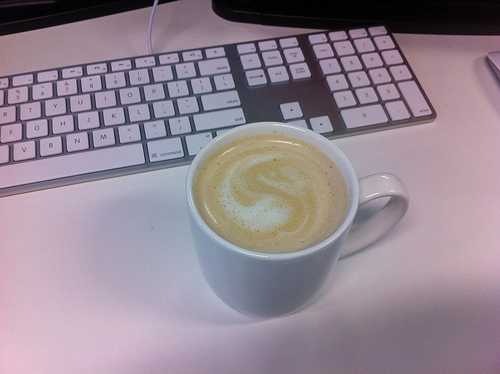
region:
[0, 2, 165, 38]
darkness behind edge of white table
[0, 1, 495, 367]
white table with flat and curved edge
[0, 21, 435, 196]
flat gray keyboard with white butons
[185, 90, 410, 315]
ceramic white mug on table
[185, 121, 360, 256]
swirl of foam on top of coffee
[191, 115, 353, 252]
yin-yang shapes on top of beverage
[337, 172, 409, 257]
curve of white handle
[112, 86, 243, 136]
square shapes next to rectangles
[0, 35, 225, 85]
border of small rectangles on edge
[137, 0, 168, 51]
curved wire leading to keyboard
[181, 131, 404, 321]
a cup of coffee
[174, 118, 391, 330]
a cup of coffee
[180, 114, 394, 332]
a cup of coffee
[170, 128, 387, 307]
a cup of coffee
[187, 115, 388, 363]
a cup of coffee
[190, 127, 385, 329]
white mug on the table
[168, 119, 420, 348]
white mug on the table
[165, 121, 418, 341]
white mug on the table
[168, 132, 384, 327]
white mug on the table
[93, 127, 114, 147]
the white letter M on the keyboard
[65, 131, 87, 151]
the white letter N on the keyboard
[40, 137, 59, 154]
the white letter B on the keyboard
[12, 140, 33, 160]
the white letter V on the keyboard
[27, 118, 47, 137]
the white letter G on the keyboard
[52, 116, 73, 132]
the white letter H on the keyboard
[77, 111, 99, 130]
the white letter J on the keyboard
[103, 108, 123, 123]
the white letter K on the keyboard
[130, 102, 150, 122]
the white letter L on the keyboard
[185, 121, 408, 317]
A white mug of coffee.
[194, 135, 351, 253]
Cream swirling in a coffee mug.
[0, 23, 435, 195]
Silver and white membrane keyboard.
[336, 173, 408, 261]
Handle of a coffee mug.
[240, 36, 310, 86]
Keys on a membrane keyboard.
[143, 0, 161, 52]
Cord of a keyboard.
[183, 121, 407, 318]
A cup full of creamed coffee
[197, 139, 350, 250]
Coffee in a white coffee mug.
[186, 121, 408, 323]
A white coffee mug on a white desk surface.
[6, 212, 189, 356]
White surface of a desk.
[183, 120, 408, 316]
a white coffee mug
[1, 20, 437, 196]
a white Apple USB keyboard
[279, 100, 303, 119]
a white up arrow key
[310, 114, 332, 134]
a white right arrow key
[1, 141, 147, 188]
a white space bar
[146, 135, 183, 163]
a white command key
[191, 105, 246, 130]
a white shift key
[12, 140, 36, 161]
a white V key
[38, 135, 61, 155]
a white B key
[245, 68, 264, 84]
A key on a keyboard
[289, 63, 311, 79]
A key on a keyboard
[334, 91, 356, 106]
A key on a keyboard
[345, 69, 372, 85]
A key on a keyboard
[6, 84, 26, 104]
A key on a keyboard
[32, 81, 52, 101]
A key on a keyboard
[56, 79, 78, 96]
A key on a keyboard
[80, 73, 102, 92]
A key on a keyboard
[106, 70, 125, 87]
A key on a keyboard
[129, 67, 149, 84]
A key on a keyboard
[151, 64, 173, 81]
A key on a keyboard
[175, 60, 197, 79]
A key on a keyboard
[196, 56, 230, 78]
A key on a keyboard